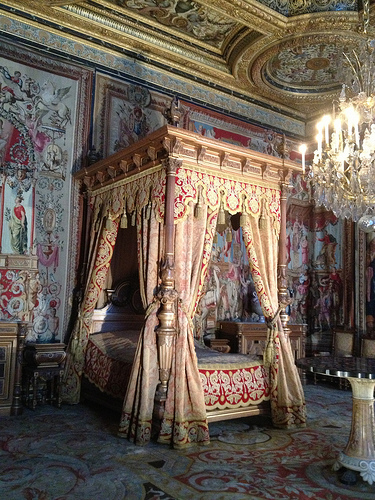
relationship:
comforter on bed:
[214, 363, 266, 412] [63, 123, 308, 440]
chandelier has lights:
[304, 78, 374, 204] [302, 112, 362, 142]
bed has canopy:
[63, 123, 308, 440] [183, 170, 272, 217]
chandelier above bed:
[304, 78, 374, 204] [63, 123, 308, 440]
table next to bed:
[14, 322, 68, 400] [63, 123, 308, 440]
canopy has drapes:
[183, 170, 272, 217] [170, 227, 228, 307]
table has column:
[304, 321, 374, 468] [335, 391, 373, 486]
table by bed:
[14, 322, 68, 400] [63, 123, 308, 440]